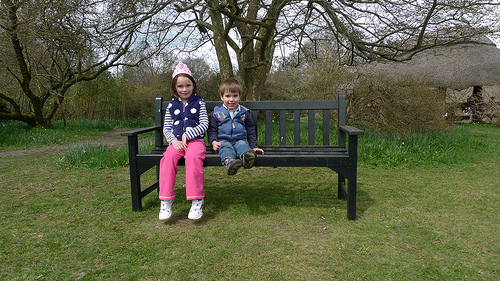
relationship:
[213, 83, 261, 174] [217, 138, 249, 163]
boy wearing jeans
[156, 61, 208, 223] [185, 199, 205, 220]
girl wearing sneaker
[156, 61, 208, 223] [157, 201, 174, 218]
girl wearing sneaker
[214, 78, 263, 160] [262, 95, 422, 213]
boy on bench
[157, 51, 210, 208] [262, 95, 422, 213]
girl on bench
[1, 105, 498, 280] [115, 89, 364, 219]
grass beneath bench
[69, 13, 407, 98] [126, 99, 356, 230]
tree behind bench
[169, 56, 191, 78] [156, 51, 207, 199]
tiara on girl's hand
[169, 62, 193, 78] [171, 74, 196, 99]
tiara on head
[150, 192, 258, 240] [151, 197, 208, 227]
shoes on feet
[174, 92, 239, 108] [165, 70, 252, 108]
smiles on faces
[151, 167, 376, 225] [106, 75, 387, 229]
shadow under bench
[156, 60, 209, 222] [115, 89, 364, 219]
child sitting on bench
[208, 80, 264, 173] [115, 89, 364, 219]
child sitting on bench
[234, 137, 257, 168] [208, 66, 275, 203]
leg on boy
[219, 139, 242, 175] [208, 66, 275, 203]
leg on boy